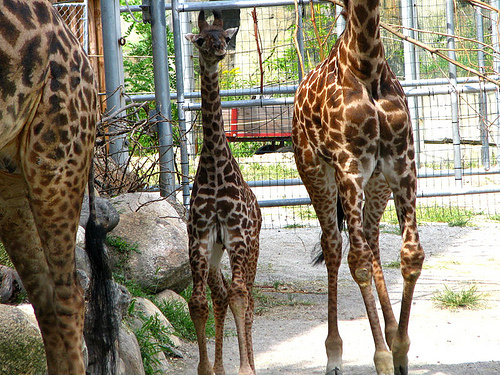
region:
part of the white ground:
[436, 305, 493, 357]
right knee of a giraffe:
[348, 246, 376, 291]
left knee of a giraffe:
[398, 249, 425, 296]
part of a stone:
[114, 200, 181, 291]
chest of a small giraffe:
[193, 186, 241, 231]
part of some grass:
[446, 285, 478, 312]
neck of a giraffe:
[344, 11, 375, 72]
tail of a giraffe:
[64, 182, 140, 348]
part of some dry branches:
[83, 98, 189, 205]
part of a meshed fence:
[423, 81, 476, 162]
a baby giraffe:
[166, 8, 298, 372]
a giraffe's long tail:
[75, 149, 116, 374]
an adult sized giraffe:
[0, 0, 95, 373]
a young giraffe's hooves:
[318, 353, 418, 374]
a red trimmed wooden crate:
[215, 95, 296, 147]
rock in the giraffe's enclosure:
[104, 189, 186, 356]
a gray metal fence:
[409, 9, 499, 208]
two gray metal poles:
[98, 2, 184, 205]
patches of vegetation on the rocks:
[108, 240, 215, 374]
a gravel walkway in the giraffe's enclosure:
[262, 231, 498, 372]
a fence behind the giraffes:
[77, 0, 499, 212]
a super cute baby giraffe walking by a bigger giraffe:
[179, 13, 279, 368]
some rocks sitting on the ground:
[93, 189, 198, 372]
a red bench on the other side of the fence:
[222, 104, 292, 142]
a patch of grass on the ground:
[436, 284, 478, 314]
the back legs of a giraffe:
[1, 6, 133, 373]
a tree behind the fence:
[120, 8, 215, 151]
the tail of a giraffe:
[74, 217, 144, 373]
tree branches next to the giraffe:
[378, 13, 499, 123]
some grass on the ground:
[246, 162, 299, 179]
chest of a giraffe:
[333, 69, 410, 164]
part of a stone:
[127, 201, 163, 302]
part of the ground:
[280, 280, 307, 372]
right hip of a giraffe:
[304, 159, 334, 237]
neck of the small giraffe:
[191, 75, 229, 142]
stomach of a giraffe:
[291, 97, 332, 154]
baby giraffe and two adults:
[50, 15, 455, 342]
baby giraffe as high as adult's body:
[175, 15, 435, 356]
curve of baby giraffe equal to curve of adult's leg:
[232, 165, 329, 337]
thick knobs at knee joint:
[180, 267, 260, 332]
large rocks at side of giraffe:
[20, 167, 215, 357]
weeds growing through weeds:
[90, 211, 230, 356]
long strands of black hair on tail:
[65, 220, 146, 365]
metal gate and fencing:
[96, 10, 471, 206]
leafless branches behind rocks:
[91, 86, 196, 197]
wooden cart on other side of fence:
[225, 97, 315, 148]